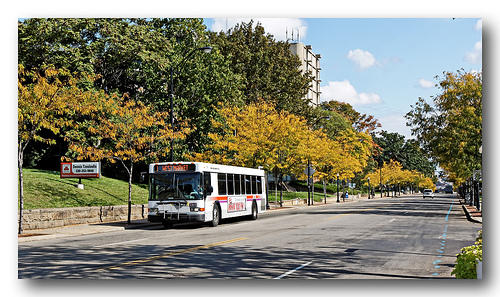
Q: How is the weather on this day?
A: It is cloudy.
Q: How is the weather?
A: It is cloudy.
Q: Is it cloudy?
A: Yes, it is cloudy.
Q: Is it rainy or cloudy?
A: It is cloudy.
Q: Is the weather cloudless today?
A: No, it is cloudy.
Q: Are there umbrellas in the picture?
A: No, there are no umbrellas.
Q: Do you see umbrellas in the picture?
A: No, there are no umbrellas.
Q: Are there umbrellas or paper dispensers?
A: No, there are no umbrellas or paper dispensers.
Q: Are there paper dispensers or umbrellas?
A: No, there are no umbrellas or paper dispensers.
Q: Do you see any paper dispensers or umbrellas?
A: No, there are no umbrellas or paper dispensers.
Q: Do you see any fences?
A: No, there are no fences.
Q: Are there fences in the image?
A: No, there are no fences.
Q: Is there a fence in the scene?
A: No, there are no fences.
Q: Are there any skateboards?
A: No, there are no skateboards.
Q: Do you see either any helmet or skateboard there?
A: No, there are no skateboards or helmets.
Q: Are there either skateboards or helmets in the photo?
A: No, there are no skateboards or helmets.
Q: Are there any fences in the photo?
A: No, there are no fences.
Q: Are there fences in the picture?
A: No, there are no fences.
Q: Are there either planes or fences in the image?
A: No, there are no fences or planes.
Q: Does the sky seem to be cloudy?
A: Yes, the sky is cloudy.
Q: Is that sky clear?
A: No, the sky is cloudy.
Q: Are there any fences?
A: No, there are no fences.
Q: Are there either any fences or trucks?
A: No, there are no fences or trucks.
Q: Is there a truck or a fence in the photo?
A: No, there are no fences or trucks.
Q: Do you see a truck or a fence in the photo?
A: No, there are no fences or trucks.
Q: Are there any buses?
A: Yes, there is a bus.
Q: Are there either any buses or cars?
A: Yes, there is a bus.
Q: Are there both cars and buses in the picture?
A: Yes, there are both a bus and a car.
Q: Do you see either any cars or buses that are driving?
A: Yes, the bus is driving.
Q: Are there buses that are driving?
A: Yes, there is a bus that is driving.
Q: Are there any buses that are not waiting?
A: Yes, there is a bus that is driving.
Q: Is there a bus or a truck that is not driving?
A: No, there is a bus but it is driving.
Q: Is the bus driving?
A: Yes, the bus is driving.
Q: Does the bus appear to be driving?
A: Yes, the bus is driving.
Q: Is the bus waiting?
A: No, the bus is driving.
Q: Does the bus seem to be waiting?
A: No, the bus is driving.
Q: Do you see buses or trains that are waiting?
A: No, there is a bus but it is driving.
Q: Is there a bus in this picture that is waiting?
A: No, there is a bus but it is driving.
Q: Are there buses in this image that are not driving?
A: No, there is a bus but it is driving.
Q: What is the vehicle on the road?
A: The vehicle is a bus.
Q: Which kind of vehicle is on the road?
A: The vehicle is a bus.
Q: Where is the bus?
A: The bus is on the road.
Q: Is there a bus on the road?
A: Yes, there is a bus on the road.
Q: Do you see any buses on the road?
A: Yes, there is a bus on the road.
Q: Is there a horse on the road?
A: No, there is a bus on the road.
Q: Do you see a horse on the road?
A: No, there is a bus on the road.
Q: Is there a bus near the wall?
A: Yes, there is a bus near the wall.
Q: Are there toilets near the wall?
A: No, there is a bus near the wall.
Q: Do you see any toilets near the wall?
A: No, there is a bus near the wall.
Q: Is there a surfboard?
A: No, there are no surfboards.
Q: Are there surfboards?
A: No, there are no surfboards.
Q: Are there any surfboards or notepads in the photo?
A: No, there are no surfboards or notepads.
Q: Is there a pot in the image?
A: No, there are no pots.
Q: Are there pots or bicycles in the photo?
A: No, there are no pots or bicycles.